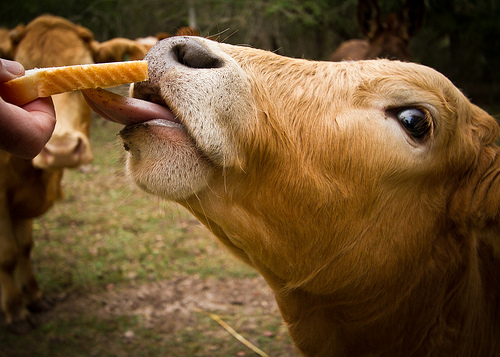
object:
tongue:
[68, 88, 167, 130]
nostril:
[170, 43, 222, 70]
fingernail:
[2, 57, 24, 77]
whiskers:
[133, 136, 247, 240]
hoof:
[3, 313, 39, 337]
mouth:
[117, 59, 239, 199]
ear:
[91, 37, 148, 64]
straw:
[206, 308, 274, 355]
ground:
[0, 118, 302, 355]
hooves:
[27, 288, 61, 315]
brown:
[313, 214, 495, 355]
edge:
[36, 60, 149, 98]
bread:
[0, 59, 151, 107]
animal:
[82, 32, 500, 357]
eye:
[383, 102, 435, 147]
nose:
[143, 27, 230, 93]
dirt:
[42, 265, 279, 335]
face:
[93, 24, 478, 204]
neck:
[284, 285, 498, 347]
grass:
[0, 117, 305, 355]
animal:
[0, 13, 145, 337]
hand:
[0, 56, 59, 163]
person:
[0, 56, 57, 160]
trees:
[57, 6, 497, 116]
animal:
[327, 0, 426, 62]